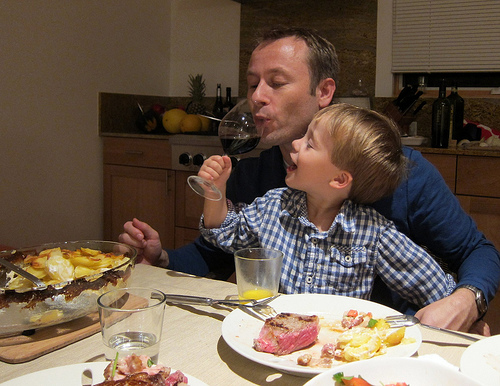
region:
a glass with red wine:
[190, 98, 271, 200]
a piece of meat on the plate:
[258, 313, 320, 352]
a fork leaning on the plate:
[386, 313, 474, 345]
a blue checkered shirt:
[211, 188, 448, 308]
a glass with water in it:
[98, 285, 165, 359]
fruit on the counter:
[163, 74, 209, 131]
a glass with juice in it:
[233, 248, 285, 300]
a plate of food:
[223, 291, 423, 363]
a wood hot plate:
[0, 294, 150, 364]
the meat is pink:
[273, 328, 315, 350]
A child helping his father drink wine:
[178, 21, 413, 292]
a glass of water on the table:
[93, 284, 169, 361]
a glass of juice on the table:
[231, 245, 286, 307]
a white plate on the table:
[216, 290, 426, 372]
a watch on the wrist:
[457, 278, 489, 318]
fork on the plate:
[385, 303, 485, 349]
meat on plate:
[251, 308, 323, 356]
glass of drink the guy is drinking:
[183, 92, 272, 207]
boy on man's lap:
[193, 98, 456, 307]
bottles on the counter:
[425, 68, 472, 145]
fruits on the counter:
[161, 70, 219, 135]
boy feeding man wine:
[196, 29, 499, 329]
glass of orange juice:
[216, 207, 300, 315]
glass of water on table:
[78, 270, 180, 379]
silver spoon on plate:
[138, 265, 287, 343]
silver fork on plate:
[372, 294, 499, 351]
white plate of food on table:
[203, 263, 423, 384]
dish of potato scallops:
[0, 217, 168, 334]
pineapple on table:
[171, 71, 219, 124]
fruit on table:
[158, 92, 233, 147]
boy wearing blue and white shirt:
[173, 149, 475, 326]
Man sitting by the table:
[115, 24, 497, 331]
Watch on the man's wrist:
[456, 281, 488, 322]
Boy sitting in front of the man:
[193, 102, 490, 336]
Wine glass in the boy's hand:
[186, 96, 268, 202]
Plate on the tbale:
[222, 292, 423, 374]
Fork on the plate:
[385, 312, 478, 342]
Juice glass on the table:
[233, 246, 283, 301]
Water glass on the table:
[98, 286, 168, 362]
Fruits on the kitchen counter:
[160, 71, 212, 133]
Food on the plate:
[253, 307, 415, 367]